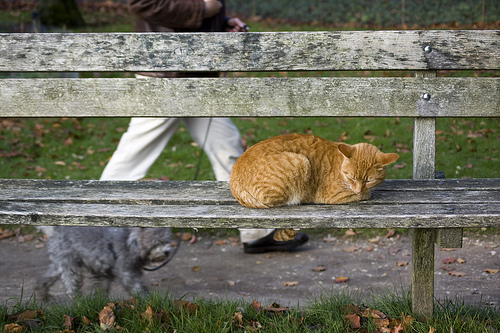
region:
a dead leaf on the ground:
[95, 297, 122, 322]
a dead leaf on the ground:
[241, 294, 264, 315]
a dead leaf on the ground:
[329, 268, 351, 289]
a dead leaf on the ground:
[484, 261, 496, 277]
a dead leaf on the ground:
[440, 255, 457, 267]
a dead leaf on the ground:
[442, 262, 464, 282]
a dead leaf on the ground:
[358, 301, 388, 317]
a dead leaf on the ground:
[397, 311, 420, 328]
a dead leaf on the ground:
[6, 318, 13, 325]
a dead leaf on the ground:
[23, 307, 56, 322]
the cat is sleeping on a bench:
[3, 5, 490, 330]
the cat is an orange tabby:
[230, 129, 398, 216]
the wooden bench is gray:
[7, 33, 497, 324]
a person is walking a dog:
[43, 5, 242, 314]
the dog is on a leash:
[136, 112, 220, 274]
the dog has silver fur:
[33, 222, 176, 308]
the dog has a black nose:
[157, 249, 178, 261]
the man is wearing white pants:
[92, 75, 273, 245]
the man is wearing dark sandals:
[241, 230, 306, 254]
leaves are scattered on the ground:
[4, 120, 499, 327]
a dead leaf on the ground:
[338, 311, 360, 327]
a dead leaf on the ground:
[400, 307, 409, 316]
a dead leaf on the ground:
[143, 305, 170, 328]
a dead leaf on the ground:
[61, 313, 81, 325]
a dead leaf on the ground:
[283, 275, 307, 289]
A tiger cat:
[228, 133, 400, 208]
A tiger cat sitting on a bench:
[138, 33, 447, 217]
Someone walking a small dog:
[14, 0, 333, 323]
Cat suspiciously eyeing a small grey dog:
[31, 118, 438, 328]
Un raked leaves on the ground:
[6, 295, 498, 331]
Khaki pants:
[100, 71, 350, 271]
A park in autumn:
[3, 3, 498, 330]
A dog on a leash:
[21, 27, 242, 304]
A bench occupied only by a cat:
[1, 28, 499, 314]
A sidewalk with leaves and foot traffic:
[4, 209, 499, 309]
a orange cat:
[220, 114, 407, 211]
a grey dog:
[2, 227, 190, 292]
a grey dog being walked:
[11, 180, 216, 305]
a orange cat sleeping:
[208, 124, 436, 232]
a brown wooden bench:
[11, 38, 496, 125]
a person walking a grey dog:
[5, 0, 239, 321]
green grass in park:
[20, 297, 454, 331]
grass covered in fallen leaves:
[5, 118, 100, 182]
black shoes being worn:
[231, 231, 312, 259]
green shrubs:
[268, 0, 496, 24]